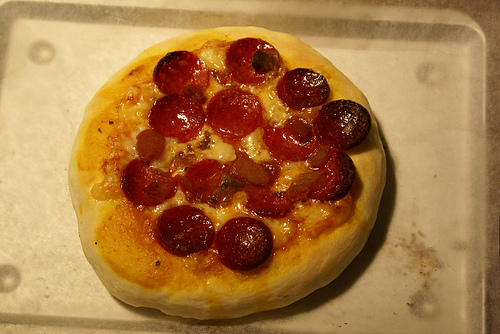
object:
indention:
[28, 40, 56, 65]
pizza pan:
[0, 0, 488, 334]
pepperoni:
[154, 205, 215, 257]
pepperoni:
[175, 156, 230, 203]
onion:
[135, 130, 167, 165]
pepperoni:
[205, 89, 262, 138]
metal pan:
[0, 0, 487, 334]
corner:
[442, 9, 488, 46]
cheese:
[259, 199, 335, 250]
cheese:
[241, 127, 270, 164]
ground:
[349, 0, 500, 334]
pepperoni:
[244, 185, 294, 217]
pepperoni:
[122, 37, 371, 271]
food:
[69, 27, 388, 321]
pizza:
[67, 26, 387, 321]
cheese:
[202, 136, 234, 161]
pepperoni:
[149, 95, 205, 144]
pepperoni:
[224, 37, 281, 87]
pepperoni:
[261, 112, 323, 162]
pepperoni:
[306, 148, 355, 202]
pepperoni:
[214, 217, 274, 272]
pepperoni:
[120, 158, 179, 207]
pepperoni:
[311, 99, 372, 150]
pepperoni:
[275, 67, 330, 109]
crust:
[69, 27, 390, 322]